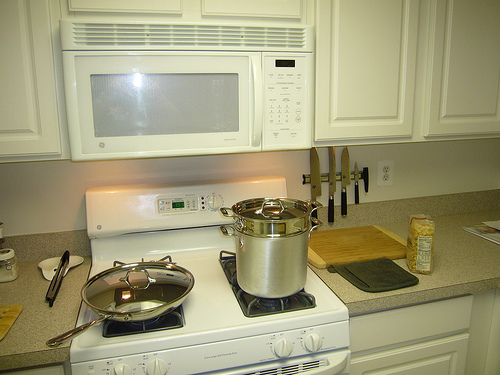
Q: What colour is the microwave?
A: White.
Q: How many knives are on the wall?
A: 4.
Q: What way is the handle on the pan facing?
A: Left.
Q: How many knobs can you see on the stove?
A: 4.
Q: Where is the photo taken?
A: Kitchen.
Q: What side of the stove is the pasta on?
A: Right.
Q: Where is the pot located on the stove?
A: Bottom right.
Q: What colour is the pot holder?
A: Grey.